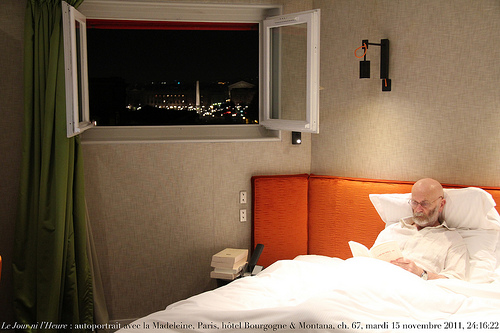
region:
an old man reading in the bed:
[348, 177, 469, 281]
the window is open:
[61, 10, 324, 137]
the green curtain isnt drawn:
[24, 5, 97, 331]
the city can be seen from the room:
[88, 43, 253, 120]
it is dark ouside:
[96, 33, 231, 70]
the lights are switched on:
[351, 92, 438, 247]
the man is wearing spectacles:
[410, 198, 447, 208]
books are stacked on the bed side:
[210, 248, 251, 280]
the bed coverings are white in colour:
[250, 265, 471, 326]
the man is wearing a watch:
[421, 267, 432, 282]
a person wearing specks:
[406, 178, 448, 233]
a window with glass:
[58, 1, 320, 144]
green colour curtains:
[23, 7, 107, 326]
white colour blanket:
[270, 260, 458, 305]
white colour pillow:
[448, 193, 496, 260]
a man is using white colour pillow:
[378, 180, 498, 262]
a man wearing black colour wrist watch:
[418, 265, 426, 283]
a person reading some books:
[346, 173, 446, 285]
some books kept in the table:
[215, 237, 267, 288]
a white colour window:
[253, 11, 348, 158]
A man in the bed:
[361, 176, 467, 276]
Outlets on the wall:
[240, 188, 248, 223]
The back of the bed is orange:
[254, 171, 499, 271]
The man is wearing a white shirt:
[380, 220, 463, 280]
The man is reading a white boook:
[349, 241, 404, 263]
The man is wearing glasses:
[411, 198, 443, 207]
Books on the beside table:
[208, 247, 248, 277]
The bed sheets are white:
[128, 258, 490, 330]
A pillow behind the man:
[372, 188, 497, 276]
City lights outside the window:
[119, 73, 256, 120]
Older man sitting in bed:
[367, 176, 465, 284]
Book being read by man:
[343, 236, 407, 273]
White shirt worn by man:
[368, 217, 466, 282]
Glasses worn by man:
[405, 196, 442, 209]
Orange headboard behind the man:
[249, 171, 496, 268]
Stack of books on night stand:
[210, 246, 248, 286]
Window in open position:
[60, 4, 324, 142]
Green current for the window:
[17, 1, 105, 329]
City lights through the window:
[128, 71, 251, 118]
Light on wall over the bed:
[353, 36, 395, 96]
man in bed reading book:
[110, 162, 496, 317]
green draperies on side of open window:
[2, 2, 107, 327]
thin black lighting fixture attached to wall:
[350, 27, 392, 92]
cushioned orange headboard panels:
[245, 171, 495, 271]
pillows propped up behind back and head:
[365, 176, 495, 271]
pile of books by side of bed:
[207, 241, 244, 286]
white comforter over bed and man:
[130, 251, 495, 316]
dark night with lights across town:
[80, 10, 262, 130]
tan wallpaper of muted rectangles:
[82, 1, 492, 311]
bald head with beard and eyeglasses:
[403, 173, 448, 228]